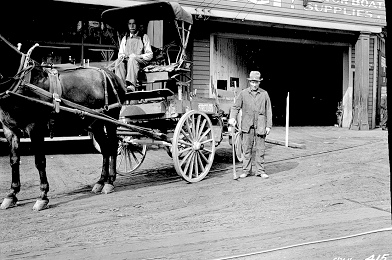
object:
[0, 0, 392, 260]
picture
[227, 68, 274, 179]
old man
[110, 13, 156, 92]
man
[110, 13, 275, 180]
two men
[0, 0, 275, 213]
black and white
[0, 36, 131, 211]
horse in harness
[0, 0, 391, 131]
building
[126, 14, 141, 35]
unsmiling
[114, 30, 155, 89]
overalls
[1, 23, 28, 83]
part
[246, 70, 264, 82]
hat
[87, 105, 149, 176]
wheel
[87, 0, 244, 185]
wagon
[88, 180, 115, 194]
hoof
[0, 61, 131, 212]
horse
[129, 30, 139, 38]
collar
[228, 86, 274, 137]
jacket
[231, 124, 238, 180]
cane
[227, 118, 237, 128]
man's hand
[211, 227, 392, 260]
line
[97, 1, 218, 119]
carraige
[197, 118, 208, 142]
spokes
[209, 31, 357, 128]
entrance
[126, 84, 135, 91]
shoes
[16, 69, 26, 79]
reins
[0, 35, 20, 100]
horse's neck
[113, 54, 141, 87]
jeans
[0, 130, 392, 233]
road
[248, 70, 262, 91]
head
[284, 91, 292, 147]
post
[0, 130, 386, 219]
ground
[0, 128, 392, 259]
in street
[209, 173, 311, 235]
unpaved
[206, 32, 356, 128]
entryway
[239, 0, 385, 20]
painted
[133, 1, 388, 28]
sign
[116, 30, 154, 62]
pair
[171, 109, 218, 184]
large spoked